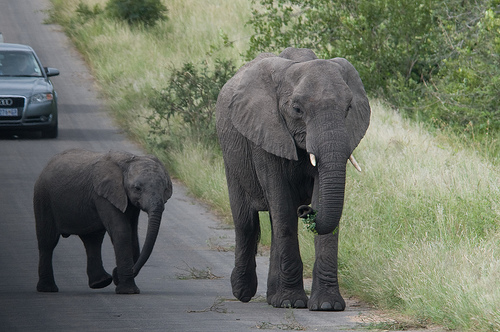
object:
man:
[4, 53, 42, 76]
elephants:
[33, 47, 372, 312]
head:
[226, 54, 372, 237]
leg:
[267, 200, 309, 309]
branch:
[301, 209, 338, 235]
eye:
[292, 107, 303, 114]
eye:
[346, 105, 350, 112]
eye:
[135, 187, 142, 191]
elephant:
[33, 147, 174, 294]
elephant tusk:
[349, 154, 361, 172]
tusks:
[310, 154, 361, 173]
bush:
[236, 0, 500, 137]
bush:
[98, 0, 174, 31]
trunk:
[131, 194, 166, 279]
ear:
[227, 57, 299, 162]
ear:
[329, 57, 371, 160]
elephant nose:
[298, 111, 349, 235]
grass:
[51, 0, 500, 332]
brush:
[136, 33, 236, 149]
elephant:
[215, 47, 371, 312]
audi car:
[1, 33, 60, 139]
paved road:
[0, 0, 432, 332]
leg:
[229, 209, 262, 303]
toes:
[308, 299, 346, 310]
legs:
[229, 210, 349, 313]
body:
[216, 46, 347, 210]